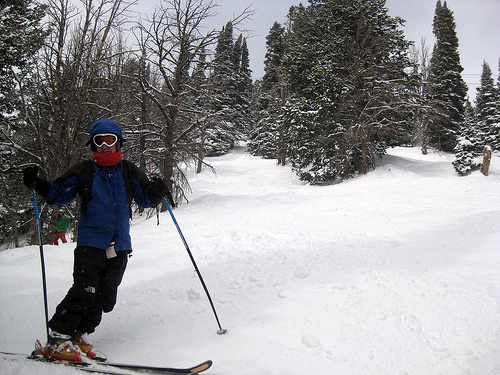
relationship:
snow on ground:
[2, 123, 498, 369] [0, 144, 497, 373]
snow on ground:
[0, 145, 499, 375] [0, 144, 497, 373]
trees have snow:
[0, 0, 499, 252] [1, 0, 498, 374]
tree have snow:
[262, 0, 413, 186] [176, 166, 496, 366]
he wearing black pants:
[22, 119, 169, 364] [45, 247, 132, 339]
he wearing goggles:
[22, 119, 169, 364] [93, 134, 118, 147]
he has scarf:
[22, 119, 169, 364] [90, 148, 124, 165]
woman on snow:
[22, 111, 209, 373] [2, 123, 498, 369]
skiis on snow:
[0, 351, 213, 373] [2, 123, 498, 369]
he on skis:
[22, 119, 169, 364] [2, 311, 225, 373]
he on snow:
[22, 119, 169, 364] [2, 123, 498, 369]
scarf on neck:
[51, 146, 122, 251] [90, 149, 123, 165]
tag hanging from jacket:
[98, 240, 130, 266] [42, 160, 153, 249]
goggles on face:
[91, 130, 120, 148] [91, 134, 116, 154]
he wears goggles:
[33, 106, 142, 367] [92, 132, 119, 152]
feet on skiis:
[30, 330, 111, 371] [3, 332, 220, 373]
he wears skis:
[22, 119, 169, 364] [23, 311, 235, 373]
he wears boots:
[22, 119, 169, 364] [47, 329, 93, 364]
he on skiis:
[22, 119, 169, 364] [26, 160, 246, 354]